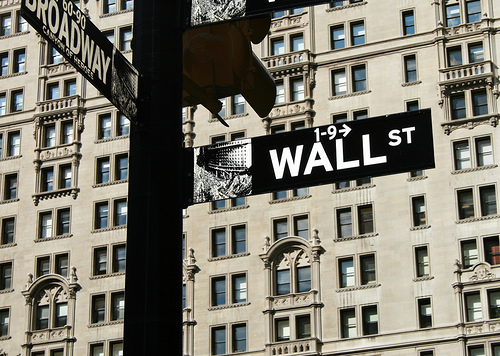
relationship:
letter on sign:
[356, 132, 389, 165] [179, 106, 436, 208]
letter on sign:
[265, 145, 304, 180] [244, 107, 435, 196]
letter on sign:
[263, 128, 397, 169] [255, 128, 426, 194]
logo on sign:
[192, 137, 254, 204] [179, 106, 436, 208]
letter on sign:
[279, 121, 408, 174] [196, 111, 446, 187]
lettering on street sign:
[25, 0, 116, 85] [15, 3, 138, 129]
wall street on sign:
[266, 122, 419, 182] [244, 105, 432, 190]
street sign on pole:
[15, 3, 138, 129] [118, 3, 202, 354]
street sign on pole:
[182, 104, 442, 208] [118, 3, 202, 354]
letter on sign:
[265, 141, 304, 179] [248, 102, 440, 206]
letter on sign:
[303, 141, 335, 177] [179, 106, 436, 208]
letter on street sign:
[329, 137, 360, 174] [182, 104, 442, 208]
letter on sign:
[383, 124, 405, 148] [205, 78, 451, 230]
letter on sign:
[401, 121, 417, 145] [244, 107, 435, 196]